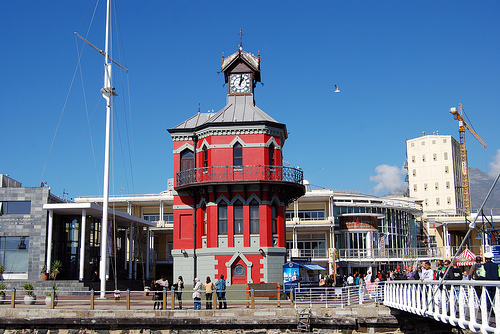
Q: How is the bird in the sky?
A: The bird is flying.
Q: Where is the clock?
A: On top of the building.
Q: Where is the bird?
A: In the sky.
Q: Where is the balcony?
A: Around the clock tower.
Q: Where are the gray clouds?
A: Behind the white building.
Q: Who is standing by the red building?
A: A group of tourists.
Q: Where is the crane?
A: By the white building.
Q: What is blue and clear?
A: The sky.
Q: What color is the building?
A: Red.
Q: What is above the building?
A: A clock.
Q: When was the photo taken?
A: Daytime.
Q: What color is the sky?
A: Blue.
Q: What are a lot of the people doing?
A: Standing.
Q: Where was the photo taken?
A: Near buildings.